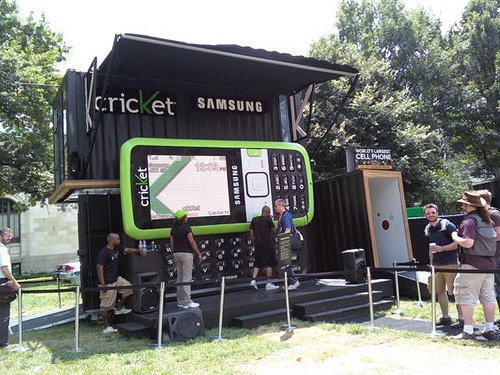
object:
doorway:
[360, 166, 415, 269]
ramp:
[381, 262, 465, 301]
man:
[453, 190, 498, 343]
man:
[422, 203, 465, 331]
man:
[273, 196, 304, 291]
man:
[94, 229, 144, 333]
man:
[0, 225, 22, 350]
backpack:
[468, 215, 499, 259]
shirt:
[97, 245, 127, 287]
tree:
[346, 7, 499, 186]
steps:
[291, 288, 393, 324]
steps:
[234, 307, 293, 327]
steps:
[117, 319, 147, 339]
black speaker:
[112, 78, 342, 279]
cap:
[173, 207, 186, 221]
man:
[249, 206, 281, 291]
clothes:
[250, 215, 278, 267]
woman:
[168, 209, 204, 309]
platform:
[130, 269, 392, 331]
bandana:
[171, 207, 186, 219]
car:
[54, 257, 82, 288]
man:
[274, 197, 299, 291]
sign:
[119, 137, 315, 241]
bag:
[288, 232, 301, 252]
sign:
[93, 88, 174, 116]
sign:
[196, 96, 264, 113]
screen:
[147, 153, 232, 219]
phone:
[119, 136, 316, 240]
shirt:
[168, 219, 195, 254]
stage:
[118, 275, 393, 327]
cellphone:
[119, 136, 315, 240]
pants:
[98, 275, 132, 310]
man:
[96, 228, 149, 335]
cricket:
[92, 89, 179, 116]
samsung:
[196, 97, 263, 113]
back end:
[57, 262, 73, 276]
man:
[418, 203, 464, 331]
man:
[447, 190, 499, 341]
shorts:
[427, 263, 455, 294]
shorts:
[452, 262, 499, 308]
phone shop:
[48, 27, 417, 335]